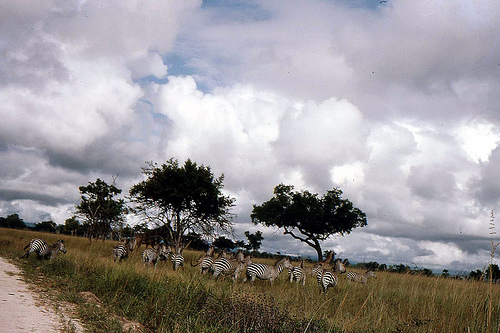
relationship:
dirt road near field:
[0, 250, 83, 330] [90, 252, 260, 332]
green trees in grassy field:
[75, 180, 124, 245] [0, 227, 499, 332]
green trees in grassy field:
[118, 158, 238, 251] [0, 227, 499, 332]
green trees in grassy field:
[252, 182, 364, 264] [0, 227, 499, 332]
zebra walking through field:
[20, 235, 70, 260] [1, 230, 499, 329]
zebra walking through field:
[110, 240, 133, 264] [1, 230, 499, 329]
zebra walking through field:
[240, 254, 295, 289] [1, 230, 499, 329]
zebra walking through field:
[207, 248, 246, 280] [1, 230, 499, 329]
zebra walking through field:
[313, 259, 347, 291] [1, 230, 499, 329]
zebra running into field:
[18, 233, 70, 266] [1, 230, 499, 329]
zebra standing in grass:
[240, 254, 295, 289] [325, 281, 446, 321]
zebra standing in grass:
[310, 254, 352, 294] [2, 227, 497, 331]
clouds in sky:
[370, 130, 465, 262] [258, 59, 435, 139]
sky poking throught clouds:
[1, 1, 498, 272] [1, 2, 166, 152]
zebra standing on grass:
[318, 254, 346, 290] [28, 234, 498, 331]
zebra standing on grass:
[240, 254, 295, 289] [28, 234, 498, 331]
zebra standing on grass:
[203, 250, 244, 271] [28, 234, 498, 331]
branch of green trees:
[247, 185, 370, 238] [252, 182, 364, 264]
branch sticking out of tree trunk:
[265, 185, 355, 242] [313, 242, 323, 262]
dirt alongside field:
[1, 260, 88, 331] [1, 230, 499, 329]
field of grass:
[1, 230, 499, 329] [65, 256, 498, 325]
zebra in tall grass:
[318, 254, 343, 295] [84, 250, 488, 328]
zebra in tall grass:
[240, 254, 295, 289] [84, 250, 488, 328]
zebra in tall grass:
[172, 245, 184, 271] [84, 250, 488, 328]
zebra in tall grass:
[32, 225, 67, 259] [84, 250, 488, 328]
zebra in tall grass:
[346, 263, 380, 287] [84, 250, 488, 328]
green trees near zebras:
[252, 182, 364, 264] [107, 242, 379, 289]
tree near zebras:
[135, 176, 210, 224] [68, 216, 392, 304]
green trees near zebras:
[118, 158, 238, 251] [150, 237, 345, 308]